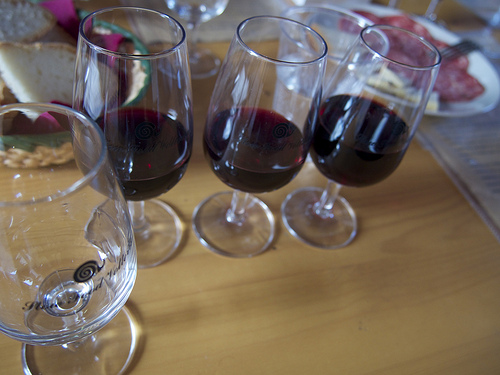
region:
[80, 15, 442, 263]
three glasses of red wine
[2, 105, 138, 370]
an empty glass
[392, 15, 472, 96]
slices of salami on a white plate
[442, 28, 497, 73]
fork propped on a plate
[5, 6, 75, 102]
slices of bread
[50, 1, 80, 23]
a magenta napkin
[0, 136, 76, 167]
a wicker basket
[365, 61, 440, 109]
white cheese on a plate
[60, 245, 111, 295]
black logo on a glass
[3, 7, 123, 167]
bread in a wicker basket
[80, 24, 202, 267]
wine glass on table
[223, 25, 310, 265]
wine glass on table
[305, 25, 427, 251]
wine glass on table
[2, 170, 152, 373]
wine glass on table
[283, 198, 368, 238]
base of wine glass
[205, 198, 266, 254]
base of wine glass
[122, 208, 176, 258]
base of wine glass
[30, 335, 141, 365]
base of wine glass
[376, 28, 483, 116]
plate with floral design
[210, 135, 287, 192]
red wine in glass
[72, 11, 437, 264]
three glasses filled with a dark liquid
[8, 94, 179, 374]
one empty glass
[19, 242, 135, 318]
black writing on the glas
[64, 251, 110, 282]
swirly black design on the glass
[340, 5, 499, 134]
plate with food on it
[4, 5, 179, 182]
light brown braided basket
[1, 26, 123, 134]
bread in the basket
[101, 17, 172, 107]
top of the basket is green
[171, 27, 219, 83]
stem of a glass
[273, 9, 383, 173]
glass of water behind the wine glasses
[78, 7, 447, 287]
three glasses with dark liquid in them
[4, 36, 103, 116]
piece of bread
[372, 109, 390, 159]
ligt reflecting off the glass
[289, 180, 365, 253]
roudnd stem of the glass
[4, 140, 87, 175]
light brown braided basket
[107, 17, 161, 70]
green trim on the basket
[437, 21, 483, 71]
utensil resting on the plate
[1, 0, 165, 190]
basket of bread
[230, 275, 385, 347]
light brown wood table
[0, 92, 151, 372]
empty wine glass on the counter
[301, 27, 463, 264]
wine glass with red wine in it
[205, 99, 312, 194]
red liquid in a clear glass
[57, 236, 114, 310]
black logo on the clear glass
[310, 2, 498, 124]
plate of food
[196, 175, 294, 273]
stem of the wine glass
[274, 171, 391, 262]
base of the wine glass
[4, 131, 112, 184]
green and brown basket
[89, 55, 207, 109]
reflections off of the glass